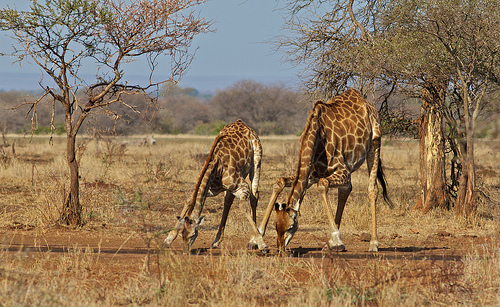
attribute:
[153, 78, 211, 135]
tree — blurred, blurry, distance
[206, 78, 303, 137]
tree — blurred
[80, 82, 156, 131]
tree — blurred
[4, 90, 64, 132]
tree — blurred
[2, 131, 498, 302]
ground — here, sandy, brown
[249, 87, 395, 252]
giraffe — here, kneeling, eating, brown, tan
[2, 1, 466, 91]
sky — blue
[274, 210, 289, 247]
fur — brown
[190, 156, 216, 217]
neck — bent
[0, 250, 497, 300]
grass — dry, dying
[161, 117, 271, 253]
giraffe — kneeling, drinking, eating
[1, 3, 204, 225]
tree — bare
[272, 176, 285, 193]
knee — bent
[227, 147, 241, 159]
spot — brown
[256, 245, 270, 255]
hoof — white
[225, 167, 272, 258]
leg — extended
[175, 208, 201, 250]
head — small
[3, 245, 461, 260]
creek — tiny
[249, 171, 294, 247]
leg — bent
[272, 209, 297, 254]
face — brown